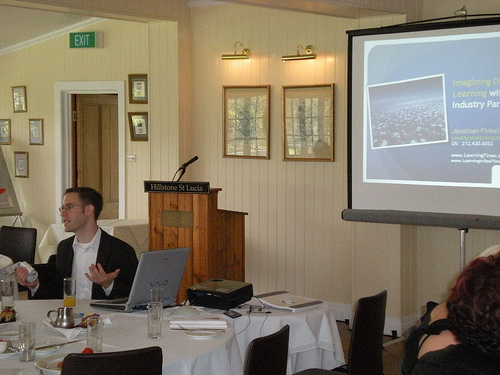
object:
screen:
[345, 25, 499, 231]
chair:
[62, 344, 162, 373]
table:
[0, 291, 339, 375]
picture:
[222, 87, 273, 160]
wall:
[185, 11, 407, 342]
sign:
[70, 30, 98, 49]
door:
[72, 92, 120, 218]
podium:
[145, 180, 249, 310]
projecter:
[187, 275, 254, 307]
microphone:
[168, 156, 203, 183]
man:
[15, 185, 141, 298]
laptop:
[91, 248, 191, 311]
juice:
[64, 276, 77, 310]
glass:
[145, 301, 164, 338]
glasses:
[57, 201, 92, 209]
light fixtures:
[212, 40, 318, 62]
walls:
[7, 14, 488, 317]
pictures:
[0, 85, 45, 177]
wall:
[4, 23, 149, 258]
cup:
[48, 307, 86, 328]